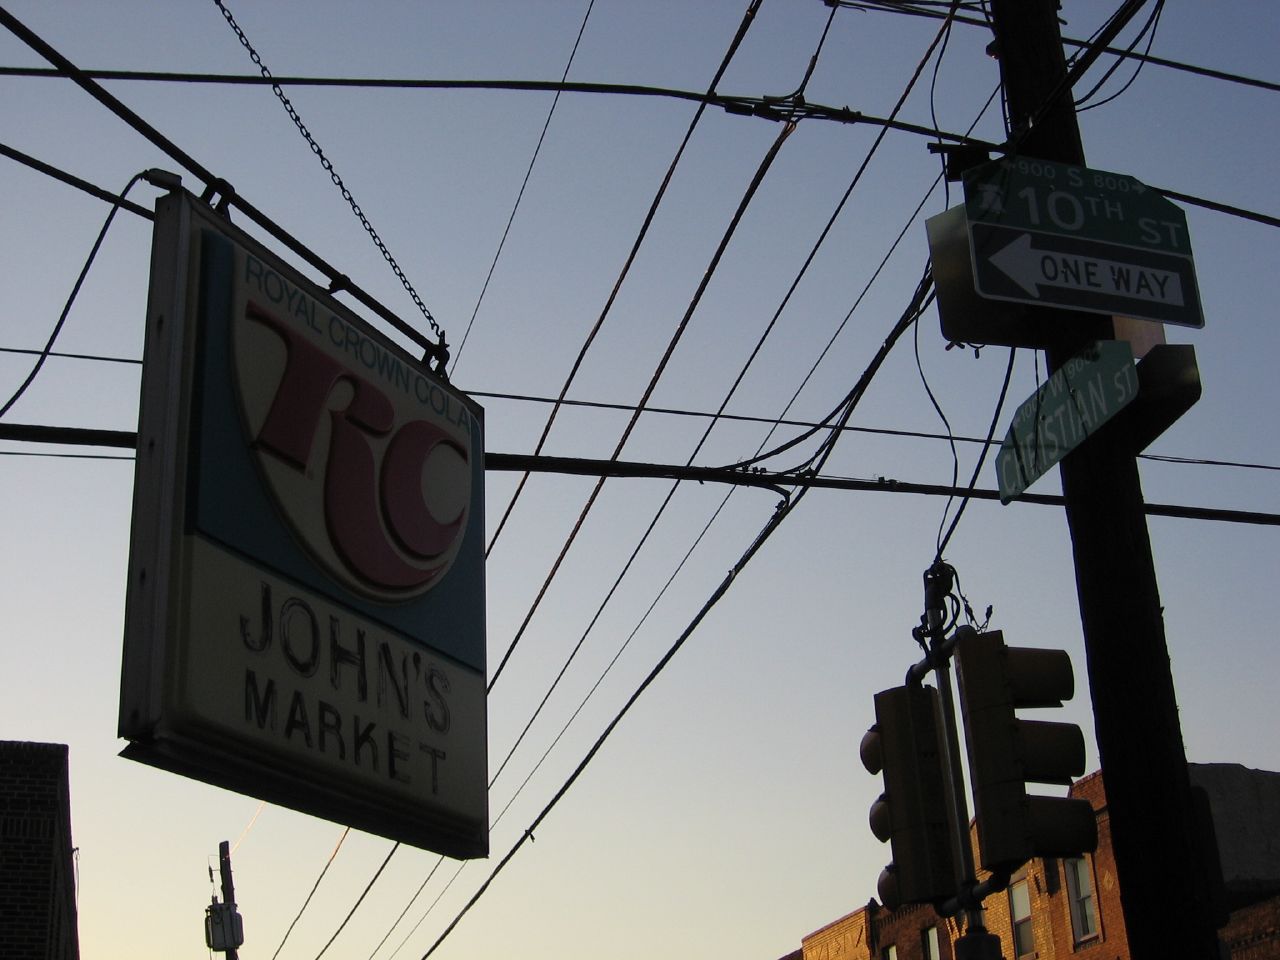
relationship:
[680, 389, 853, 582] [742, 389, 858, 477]
cables has bend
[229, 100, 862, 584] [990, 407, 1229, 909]
cables on pole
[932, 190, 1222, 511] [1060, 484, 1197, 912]
street signs on pole